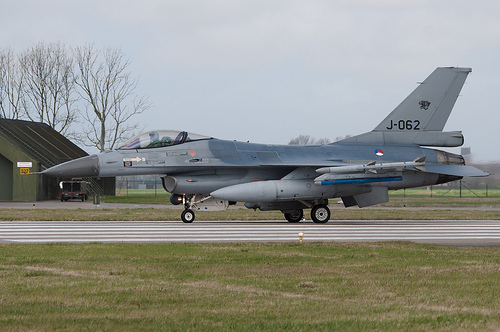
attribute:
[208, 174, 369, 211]
missile — large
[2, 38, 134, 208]
trees — bare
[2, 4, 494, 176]
sky — overcast, blue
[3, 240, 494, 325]
patches — brown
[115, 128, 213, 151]
cockpit — clear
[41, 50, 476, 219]
plane — grey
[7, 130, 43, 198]
building — green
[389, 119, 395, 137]
letter — black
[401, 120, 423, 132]
number — black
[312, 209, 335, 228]
wheel — black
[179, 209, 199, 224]
wheel — black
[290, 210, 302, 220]
wheel — black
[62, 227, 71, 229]
line — white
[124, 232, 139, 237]
line — white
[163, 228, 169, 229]
line — white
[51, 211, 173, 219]
grass — green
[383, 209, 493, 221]
grass — green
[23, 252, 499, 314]
grass — green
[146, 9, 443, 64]
sky — overcast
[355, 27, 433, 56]
cloud — gray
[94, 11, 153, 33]
cloud — gray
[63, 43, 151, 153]
leafless tree — brown, tall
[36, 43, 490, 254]
plane — grey